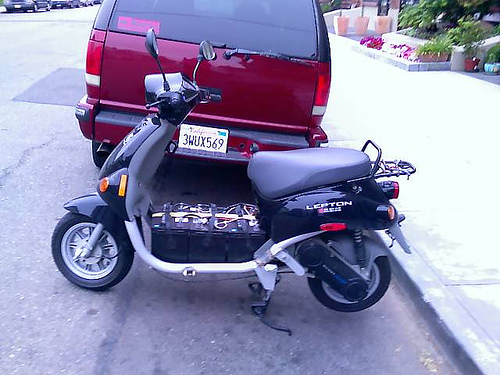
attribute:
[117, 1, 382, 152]
car — red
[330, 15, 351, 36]
clay pot — orange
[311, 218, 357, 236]
reflector — red